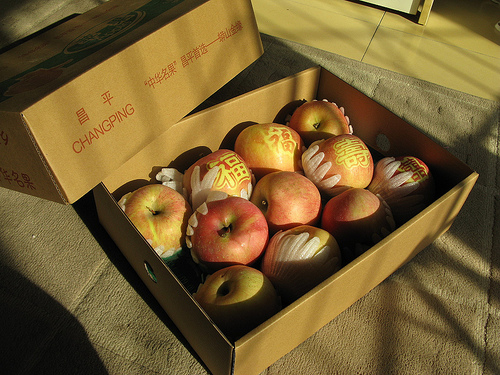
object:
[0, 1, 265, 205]
lid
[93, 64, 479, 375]
box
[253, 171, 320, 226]
fruit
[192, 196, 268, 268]
apple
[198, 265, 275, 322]
apple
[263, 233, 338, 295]
cover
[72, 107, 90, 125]
words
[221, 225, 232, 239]
stem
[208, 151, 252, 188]
lettering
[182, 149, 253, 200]
apple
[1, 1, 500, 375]
rug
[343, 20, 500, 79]
tiles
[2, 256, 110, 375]
shadows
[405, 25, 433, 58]
reflection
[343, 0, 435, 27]
furniture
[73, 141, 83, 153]
word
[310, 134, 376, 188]
apples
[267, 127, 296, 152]
lettering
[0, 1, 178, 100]
design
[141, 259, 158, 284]
hole